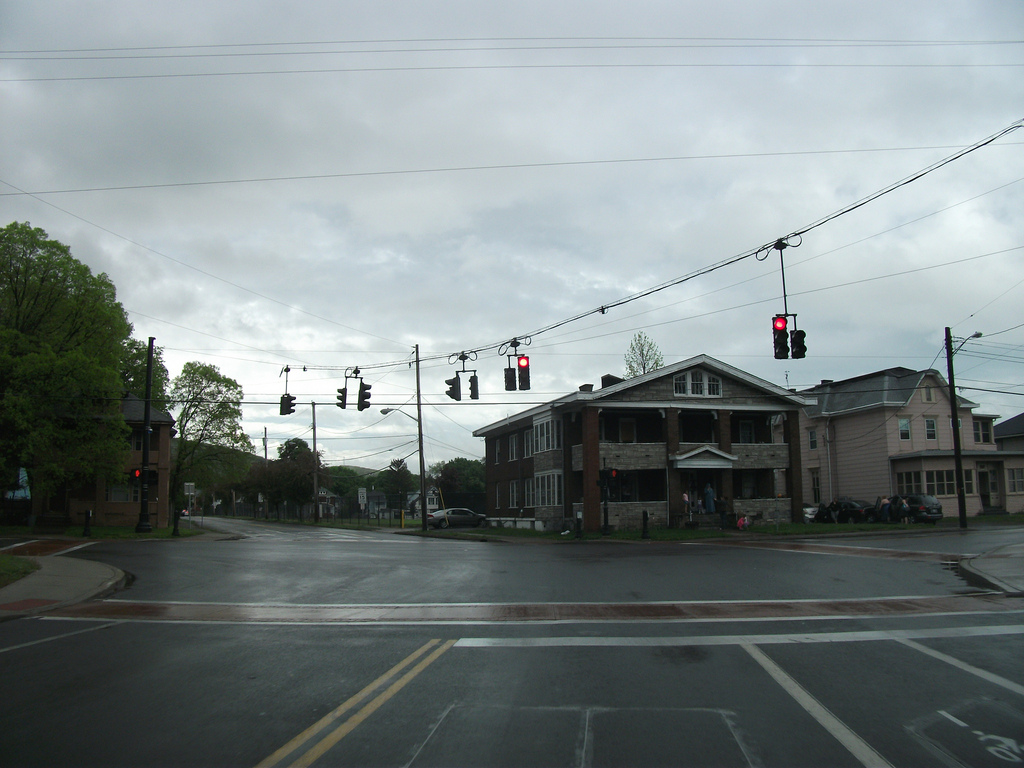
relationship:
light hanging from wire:
[512, 354, 536, 389] [269, 112, 996, 394]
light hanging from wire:
[771, 313, 789, 361] [166, 124, 1014, 423]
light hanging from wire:
[794, 328, 812, 357] [153, 125, 1007, 398]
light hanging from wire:
[498, 353, 527, 390] [153, 125, 1007, 398]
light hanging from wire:
[457, 381, 483, 408] [17, 116, 1014, 402]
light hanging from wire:
[444, 373, 462, 400] [166, 124, 1014, 423]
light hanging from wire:
[280, 395, 296, 415] [166, 124, 1014, 423]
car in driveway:
[432, 502, 484, 528] [417, 492, 487, 529]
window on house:
[598, 416, 681, 449] [475, 353, 815, 531]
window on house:
[894, 412, 910, 430] [799, 364, 977, 525]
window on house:
[924, 414, 944, 445] [770, 367, 1024, 518]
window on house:
[535, 420, 549, 453] [477, 356, 821, 544]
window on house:
[537, 474, 551, 503] [475, 353, 815, 531]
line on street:
[740, 637, 883, 765] [10, 468, 1017, 760]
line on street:
[455, 628, 1007, 659] [10, 468, 1017, 760]